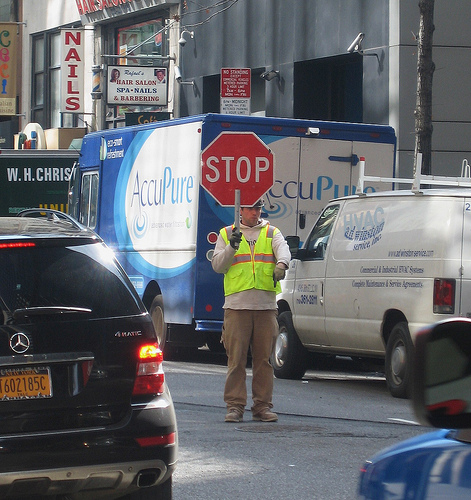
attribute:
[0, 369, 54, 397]
license plate — yellow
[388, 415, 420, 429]
line — white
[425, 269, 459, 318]
tail light — red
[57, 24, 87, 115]
sign — nails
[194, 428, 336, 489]
asphalt — black 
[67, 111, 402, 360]
truck — blue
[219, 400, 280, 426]
boots — large, brown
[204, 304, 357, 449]
pants — khaki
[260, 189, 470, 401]
van — white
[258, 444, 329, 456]
asphalt — black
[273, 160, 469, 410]
van — white, paneled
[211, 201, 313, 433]
man — wearing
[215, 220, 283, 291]
vest — bright colored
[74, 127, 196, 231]
van — white , Blue 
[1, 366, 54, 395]
plate — new york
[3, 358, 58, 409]
license plate — yellow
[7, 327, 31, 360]
metal logo — grey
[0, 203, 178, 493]
suv — black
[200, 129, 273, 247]
sign — red , white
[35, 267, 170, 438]
suv — black, mercedes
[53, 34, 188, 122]
salon — nail